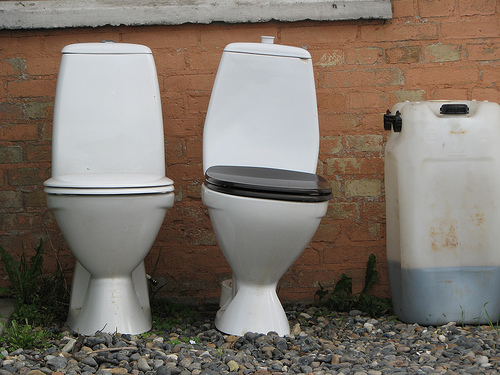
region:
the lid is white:
[39, 157, 171, 198]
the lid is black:
[197, 150, 340, 207]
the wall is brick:
[327, 65, 378, 185]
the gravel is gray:
[142, 346, 292, 368]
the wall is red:
[347, 43, 473, 73]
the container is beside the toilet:
[378, 86, 498, 326]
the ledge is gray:
[34, 0, 400, 24]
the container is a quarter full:
[378, 82, 498, 337]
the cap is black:
[431, 99, 473, 124]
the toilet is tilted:
[210, 12, 328, 347]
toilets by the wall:
[25, 29, 330, 343]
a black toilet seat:
[201, 162, 336, 204]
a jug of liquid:
[373, 87, 498, 337]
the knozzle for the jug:
[373, 108, 400, 143]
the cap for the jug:
[438, 100, 475, 120]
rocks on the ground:
[55, 323, 337, 372]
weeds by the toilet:
[3, 235, 70, 340]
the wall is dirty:
[0, 74, 43, 296]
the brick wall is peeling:
[420, 14, 492, 93]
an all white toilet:
[41, 39, 170, 349]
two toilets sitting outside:
[42, 37, 346, 367]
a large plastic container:
[387, 97, 487, 318]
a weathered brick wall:
[10, 27, 496, 283]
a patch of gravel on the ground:
[32, 334, 457, 372]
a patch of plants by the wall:
[15, 301, 252, 347]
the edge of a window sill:
[0, 5, 401, 23]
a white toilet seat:
[57, 178, 177, 204]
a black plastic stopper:
[375, 109, 410, 128]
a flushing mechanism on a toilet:
[253, 23, 293, 62]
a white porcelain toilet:
[40, 41, 178, 346]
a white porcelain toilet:
[197, 30, 334, 351]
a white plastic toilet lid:
[41, 170, 173, 197]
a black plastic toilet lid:
[200, 161, 330, 204]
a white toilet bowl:
[199, 187, 331, 334]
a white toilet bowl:
[39, 195, 177, 337]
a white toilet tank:
[47, 47, 170, 170]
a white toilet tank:
[201, 44, 324, 183]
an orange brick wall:
[11, 2, 492, 292]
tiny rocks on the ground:
[340, 326, 404, 373]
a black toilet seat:
[207, 153, 329, 203]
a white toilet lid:
[57, 166, 168, 196]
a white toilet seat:
[50, 176, 165, 191]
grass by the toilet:
[26, 301, 52, 333]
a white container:
[377, 114, 498, 256]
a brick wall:
[320, 33, 447, 86]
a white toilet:
[41, 90, 169, 313]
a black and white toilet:
[212, 38, 322, 322]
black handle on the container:
[378, 106, 407, 139]